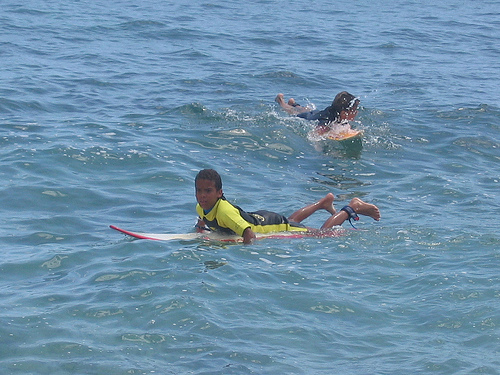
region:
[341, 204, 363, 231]
ankle strap for surfboard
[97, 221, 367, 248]
a red and white surfboard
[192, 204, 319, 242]
black and yellow wetsuit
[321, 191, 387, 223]
a boy's bare feet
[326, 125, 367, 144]
front of an orange surfboard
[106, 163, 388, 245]
a boy laying on a surfboard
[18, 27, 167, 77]
calm blue ocean water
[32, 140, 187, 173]
ripples on top of water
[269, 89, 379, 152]
a child splashing in the water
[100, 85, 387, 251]
two kids playing on surfboards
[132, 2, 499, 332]
children in teh water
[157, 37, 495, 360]
children on surfboards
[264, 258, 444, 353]
a body of water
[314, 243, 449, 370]
a body of blue water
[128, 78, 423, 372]
children laying on surfboards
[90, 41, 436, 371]
children surfing in the water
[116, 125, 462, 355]
a child wearing a swimsuit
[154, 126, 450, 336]
a child with long hair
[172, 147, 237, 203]
head of a person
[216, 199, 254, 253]
arm of a person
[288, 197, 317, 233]
leg of a person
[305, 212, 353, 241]
leg of a person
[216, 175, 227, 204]
ear of a person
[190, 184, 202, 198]
eye of a person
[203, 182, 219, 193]
eye of a person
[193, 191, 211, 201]
nose of a person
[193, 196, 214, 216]
mouth of a person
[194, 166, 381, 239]
A boy on a surf board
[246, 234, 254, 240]
Elbow sticking out of the water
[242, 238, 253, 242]
Arm in ther water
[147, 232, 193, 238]
a surfing board in the water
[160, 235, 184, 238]
White surface of the board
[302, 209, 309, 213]
Leg of boy wet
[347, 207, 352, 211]
A strap on the leg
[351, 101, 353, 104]
Water splashing on the hair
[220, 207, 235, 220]
A yellow wet suit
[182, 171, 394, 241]
the kid is surfing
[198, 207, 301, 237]
the swimsuit is yellow and black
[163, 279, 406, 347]
the water is blue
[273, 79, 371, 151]
the boy is on the surfboard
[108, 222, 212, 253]
the surfboard is white and red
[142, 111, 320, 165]
light is shinning in the water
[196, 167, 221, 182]
the hair is brown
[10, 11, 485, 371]
the photo was taken during the day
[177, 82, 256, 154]
the water is blue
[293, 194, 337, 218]
the legs are wet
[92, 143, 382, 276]
boy on a surfboard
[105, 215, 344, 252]
surfboard on the water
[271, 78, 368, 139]
dark clothing on the boy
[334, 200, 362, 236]
ankle cable to the surfboard